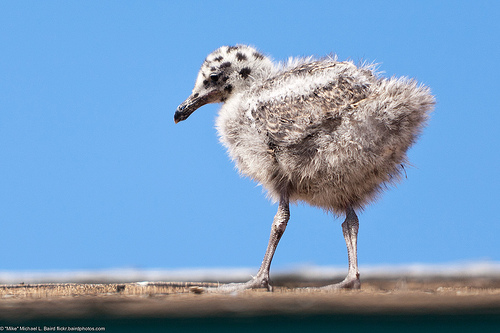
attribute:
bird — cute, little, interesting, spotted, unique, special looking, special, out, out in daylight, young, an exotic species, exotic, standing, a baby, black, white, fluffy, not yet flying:
[174, 43, 438, 293]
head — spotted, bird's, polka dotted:
[174, 43, 276, 123]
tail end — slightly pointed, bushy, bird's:
[290, 51, 437, 218]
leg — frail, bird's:
[190, 193, 291, 295]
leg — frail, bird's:
[319, 207, 362, 291]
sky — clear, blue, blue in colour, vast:
[1, 1, 500, 273]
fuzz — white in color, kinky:
[192, 44, 437, 218]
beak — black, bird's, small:
[174, 88, 223, 123]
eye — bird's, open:
[209, 72, 218, 81]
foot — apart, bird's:
[190, 275, 274, 294]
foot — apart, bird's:
[319, 273, 361, 290]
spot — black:
[213, 55, 224, 62]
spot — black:
[227, 45, 239, 53]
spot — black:
[218, 61, 231, 70]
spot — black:
[236, 52, 247, 61]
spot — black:
[239, 67, 251, 79]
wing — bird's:
[248, 59, 372, 147]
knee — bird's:
[271, 209, 291, 234]